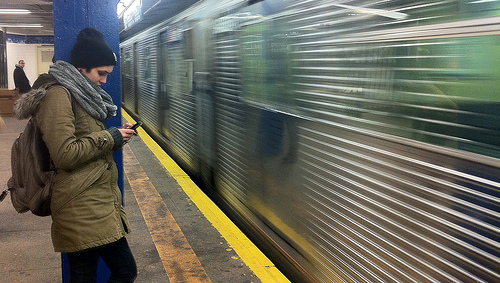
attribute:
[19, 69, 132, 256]
jacket — brown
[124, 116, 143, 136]
phone — black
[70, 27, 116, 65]
hat — black, knit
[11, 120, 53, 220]
backpack — brown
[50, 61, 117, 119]
scarf — grey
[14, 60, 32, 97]
man — waiting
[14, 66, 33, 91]
jacket — black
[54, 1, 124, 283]
beam — blue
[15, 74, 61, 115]
hood — furry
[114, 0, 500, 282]
train — silver, speeding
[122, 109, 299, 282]
line — yellow, cautionary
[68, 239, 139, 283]
pants — black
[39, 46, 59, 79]
door — off-white